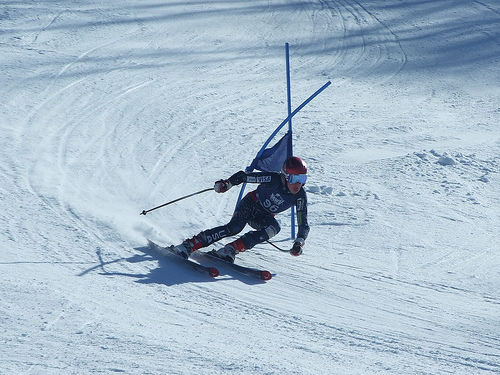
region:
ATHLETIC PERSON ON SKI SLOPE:
[171, 130, 336, 282]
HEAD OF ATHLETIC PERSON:
[273, 154, 316, 196]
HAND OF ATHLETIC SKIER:
[211, 178, 233, 200]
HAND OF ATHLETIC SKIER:
[282, 240, 304, 257]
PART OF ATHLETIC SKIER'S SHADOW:
[146, 259, 192, 286]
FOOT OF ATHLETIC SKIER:
[168, 244, 193, 264]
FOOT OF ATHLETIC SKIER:
[208, 245, 239, 262]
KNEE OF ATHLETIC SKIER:
[261, 221, 288, 242]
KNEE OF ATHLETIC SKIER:
[224, 217, 244, 237]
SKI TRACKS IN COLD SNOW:
[71, 88, 186, 150]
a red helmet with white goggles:
[282, 157, 309, 187]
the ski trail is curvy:
[0, 13, 477, 373]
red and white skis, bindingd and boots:
[143, 233, 271, 293]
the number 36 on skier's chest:
[258, 197, 281, 218]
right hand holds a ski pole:
[138, 188, 220, 218]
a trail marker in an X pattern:
[228, 44, 332, 233]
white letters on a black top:
[246, 173, 315, 233]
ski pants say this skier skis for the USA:
[201, 227, 233, 244]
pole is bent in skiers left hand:
[260, 237, 297, 263]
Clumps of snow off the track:
[288, 143, 499, 206]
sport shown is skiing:
[132, 157, 312, 282]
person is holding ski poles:
[139, 185, 297, 260]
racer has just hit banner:
[235, 40, 330, 235]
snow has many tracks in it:
[9, 1, 497, 373]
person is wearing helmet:
[282, 158, 308, 176]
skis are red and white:
[146, 237, 273, 282]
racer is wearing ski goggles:
[281, 170, 308, 184]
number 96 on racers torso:
[262, 194, 279, 211]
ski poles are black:
[140, 181, 300, 256]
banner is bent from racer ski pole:
[232, 42, 331, 218]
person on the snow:
[132, 80, 421, 291]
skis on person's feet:
[151, 214, 286, 280]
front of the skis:
[178, 251, 276, 303]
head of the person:
[268, 143, 318, 202]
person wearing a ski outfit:
[156, 154, 331, 296]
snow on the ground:
[313, 244, 421, 339]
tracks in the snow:
[216, 292, 332, 355]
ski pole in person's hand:
[128, 166, 227, 231]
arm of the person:
[209, 155, 280, 205]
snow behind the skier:
[50, 74, 197, 147]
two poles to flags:
[244, 37, 341, 128]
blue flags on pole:
[250, 133, 292, 171]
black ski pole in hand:
[128, 185, 220, 235]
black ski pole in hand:
[263, 243, 290, 260]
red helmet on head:
[282, 154, 308, 176]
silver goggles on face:
[286, 173, 311, 184]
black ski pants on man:
[193, 201, 275, 258]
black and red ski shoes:
[171, 238, 201, 257]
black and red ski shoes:
[220, 227, 264, 261]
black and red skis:
[224, 261, 279, 290]